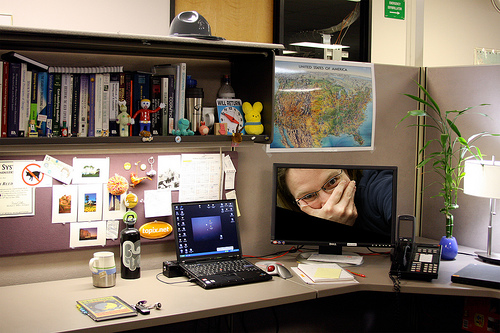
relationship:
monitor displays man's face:
[271, 163, 397, 248] [286, 169, 355, 217]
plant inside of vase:
[395, 77, 500, 236] [438, 237, 458, 261]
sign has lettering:
[385, 1, 404, 20] [388, 2, 402, 10]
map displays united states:
[266, 56, 375, 158] [275, 73, 373, 148]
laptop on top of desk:
[171, 199, 271, 287] [0, 27, 500, 333]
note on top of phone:
[419, 252, 435, 263] [390, 238, 442, 321]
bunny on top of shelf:
[242, 102, 264, 134] [0, 135, 268, 157]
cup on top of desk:
[90, 251, 116, 287] [0, 27, 500, 333]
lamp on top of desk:
[463, 156, 499, 263] [0, 27, 500, 333]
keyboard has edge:
[182, 259, 256, 276] [196, 267, 261, 276]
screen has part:
[175, 204, 236, 255] [221, 224, 226, 234]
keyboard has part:
[182, 259, 256, 276] [198, 264, 206, 272]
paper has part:
[315, 267, 342, 278] [334, 270, 336, 272]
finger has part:
[325, 180, 344, 210] [331, 198, 334, 203]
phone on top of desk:
[390, 238, 442, 321] [0, 27, 500, 333]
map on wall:
[266, 56, 375, 158] [237, 61, 420, 257]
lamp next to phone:
[463, 156, 499, 263] [390, 238, 442, 321]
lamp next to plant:
[463, 156, 499, 263] [395, 77, 500, 236]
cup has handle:
[90, 251, 116, 287] [88, 259, 97, 274]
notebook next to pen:
[297, 263, 354, 281] [346, 267, 364, 277]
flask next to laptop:
[120, 215, 141, 277] [171, 199, 271, 287]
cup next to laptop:
[90, 251, 116, 287] [171, 199, 271, 287]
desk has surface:
[0, 27, 500, 333] [0, 235, 500, 333]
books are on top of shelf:
[1, 52, 187, 136] [0, 135, 268, 157]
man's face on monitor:
[286, 169, 355, 217] [271, 163, 397, 248]